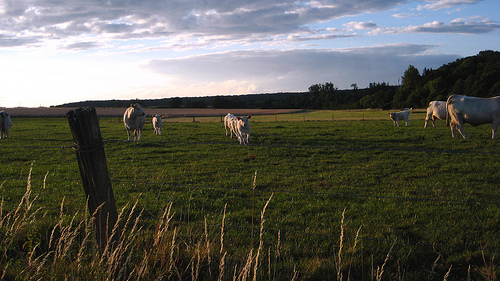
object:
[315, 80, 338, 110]
tree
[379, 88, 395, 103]
tree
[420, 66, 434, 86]
tree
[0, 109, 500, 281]
grass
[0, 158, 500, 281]
yellow weeds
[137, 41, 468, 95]
clouds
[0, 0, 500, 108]
sky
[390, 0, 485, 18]
cloud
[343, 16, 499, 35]
cloud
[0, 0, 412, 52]
cloud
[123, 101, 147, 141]
cow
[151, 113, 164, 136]
cow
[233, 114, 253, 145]
cow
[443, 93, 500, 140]
cow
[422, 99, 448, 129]
cow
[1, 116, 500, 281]
pasture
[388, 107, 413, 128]
cow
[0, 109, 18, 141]
cow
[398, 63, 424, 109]
tree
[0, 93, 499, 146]
cattle herd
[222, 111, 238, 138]
cows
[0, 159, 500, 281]
plants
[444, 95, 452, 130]
tail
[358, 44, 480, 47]
sky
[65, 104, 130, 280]
fence post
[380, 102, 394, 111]
bush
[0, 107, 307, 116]
dirt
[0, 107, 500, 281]
field